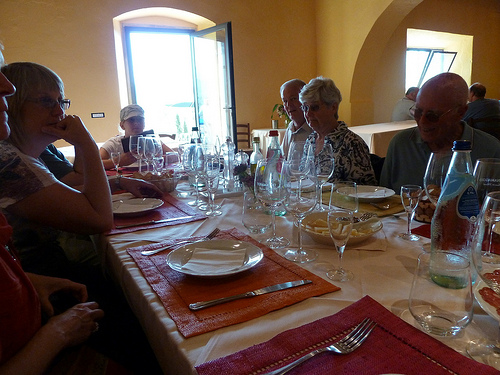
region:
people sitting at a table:
[1, 46, 494, 371]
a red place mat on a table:
[188, 295, 498, 373]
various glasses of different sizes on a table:
[108, 134, 498, 342]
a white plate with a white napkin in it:
[161, 235, 263, 277]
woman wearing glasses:
[23, 93, 70, 110]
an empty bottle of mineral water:
[431, 137, 480, 288]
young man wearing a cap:
[116, 104, 143, 119]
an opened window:
[193, 20, 238, 152]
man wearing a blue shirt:
[382, 126, 498, 195]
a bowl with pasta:
[296, 206, 381, 241]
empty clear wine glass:
[318, 205, 363, 274]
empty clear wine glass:
[282, 172, 317, 254]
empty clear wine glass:
[257, 166, 284, 233]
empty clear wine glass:
[196, 158, 220, 207]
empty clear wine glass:
[186, 149, 206, 211]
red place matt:
[132, 222, 297, 329]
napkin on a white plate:
[157, 212, 263, 287]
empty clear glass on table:
[410, 236, 475, 348]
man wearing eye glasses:
[396, 105, 452, 127]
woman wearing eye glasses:
[294, 102, 343, 121]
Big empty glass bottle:
[430, 140, 482, 287]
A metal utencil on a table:
[189, 278, 312, 309]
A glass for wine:
[327, 180, 357, 280]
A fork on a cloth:
[257, 318, 375, 373]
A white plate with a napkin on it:
[166, 238, 263, 277]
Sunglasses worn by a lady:
[298, 103, 323, 112]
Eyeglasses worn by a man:
[406, 105, 458, 117]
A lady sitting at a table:
[97, 106, 181, 167]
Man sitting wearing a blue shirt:
[467, 81, 499, 123]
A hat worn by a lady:
[119, 105, 144, 119]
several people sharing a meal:
[0, 46, 490, 356]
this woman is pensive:
[8, 62, 113, 236]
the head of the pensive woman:
[11, 62, 74, 157]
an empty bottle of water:
[430, 140, 481, 282]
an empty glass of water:
[408, 253, 475, 337]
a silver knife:
[174, 280, 312, 310]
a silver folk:
[267, 319, 374, 373]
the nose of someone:
[1, 70, 17, 99]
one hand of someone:
[46, 304, 106, 354]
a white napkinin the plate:
[163, 239, 263, 279]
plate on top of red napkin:
[162, 233, 257, 275]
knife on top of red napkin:
[181, 271, 313, 306]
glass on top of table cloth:
[326, 177, 356, 282]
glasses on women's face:
[31, 95, 73, 111]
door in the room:
[189, 25, 231, 144]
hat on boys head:
[120, 105, 145, 118]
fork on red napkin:
[260, 313, 375, 373]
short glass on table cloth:
[401, 181, 415, 238]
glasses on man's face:
[409, 106, 451, 121]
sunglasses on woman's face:
[298, 100, 326, 114]